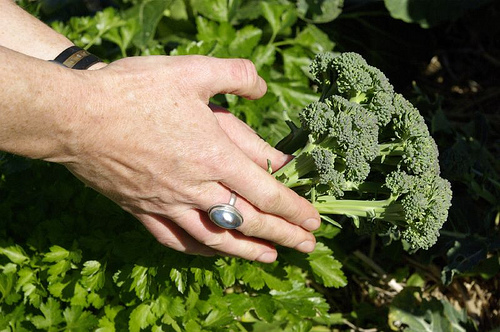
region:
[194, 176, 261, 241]
silver ring on the hand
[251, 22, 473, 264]
a bunch of green broccoli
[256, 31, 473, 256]
green vegetable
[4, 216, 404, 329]
green leaves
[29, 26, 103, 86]
black and brown bracelet on the wrist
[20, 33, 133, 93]
bracelet is near the green leaves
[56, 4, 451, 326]
green leaves are near the broccoli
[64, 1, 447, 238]
green leaves are lighter than the broccoli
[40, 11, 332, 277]
hands are together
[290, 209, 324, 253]
nails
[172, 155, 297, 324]
the ring in middle finger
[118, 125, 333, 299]
the ring in middle finger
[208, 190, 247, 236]
mood ring on womans finger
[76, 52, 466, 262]
the person is holding a few stalks of broccolli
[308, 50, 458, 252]
the broccolli is green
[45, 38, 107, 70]
the person has a watch on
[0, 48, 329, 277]
the person has freckles or age spots on their arm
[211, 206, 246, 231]
the colors inside the ring are blue and black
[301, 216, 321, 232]
the persons fingernails are clipped and clean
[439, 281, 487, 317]
sunlight filtering through the leaves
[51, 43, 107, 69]
the watch bank is brown and green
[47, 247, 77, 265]
the leaves of the plant are green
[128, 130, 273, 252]
a large silver ring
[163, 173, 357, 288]
the ring is oval shaped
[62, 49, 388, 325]
the hand is white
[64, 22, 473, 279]
the hand is grabbing broccoli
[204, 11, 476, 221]
a head of broccoli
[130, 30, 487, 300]
broccoli is a flower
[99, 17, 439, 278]
hands in front of plants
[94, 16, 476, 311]
this person is gardening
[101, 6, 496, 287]
the act of picking food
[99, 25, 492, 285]
the broccoli is fresh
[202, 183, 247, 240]
The person have a ring on finger.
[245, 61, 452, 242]
The peron is holding broccoli.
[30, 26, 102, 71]
The person is wearing a watch.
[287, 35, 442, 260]
The broccoli is green.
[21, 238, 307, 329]
The plants are green.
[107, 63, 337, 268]
The hands of a person.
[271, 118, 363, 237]
The stems of the broccoli is green.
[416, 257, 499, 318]
A dead leaf on the ground.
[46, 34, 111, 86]
The watch is silver and black.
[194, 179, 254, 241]
The ring is oval shaped